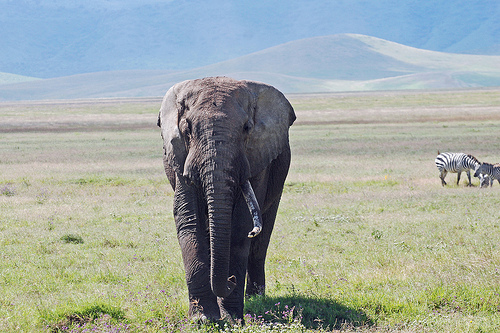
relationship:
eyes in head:
[240, 120, 250, 133] [156, 72, 296, 296]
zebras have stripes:
[433, 151, 489, 187] [437, 152, 448, 169]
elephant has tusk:
[158, 71, 296, 332] [239, 177, 264, 239]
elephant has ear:
[158, 71, 296, 332] [245, 76, 297, 175]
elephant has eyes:
[158, 71, 296, 332] [240, 120, 250, 133]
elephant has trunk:
[158, 71, 296, 332] [200, 174, 240, 300]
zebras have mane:
[433, 151, 489, 187] [467, 152, 485, 166]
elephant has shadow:
[158, 71, 296, 332] [243, 294, 378, 329]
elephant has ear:
[158, 71, 296, 332] [152, 89, 187, 181]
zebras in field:
[433, 151, 489, 187] [5, 87, 498, 332]